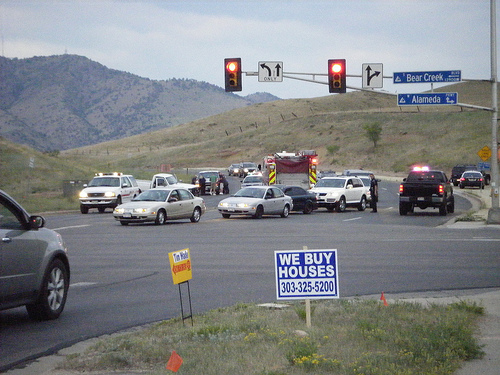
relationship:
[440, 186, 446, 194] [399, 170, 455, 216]
brake lights on back of pick up truck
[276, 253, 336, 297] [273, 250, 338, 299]
ad on sign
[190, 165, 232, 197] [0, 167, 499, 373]
auto accident on street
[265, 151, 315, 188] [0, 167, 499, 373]
emergency vehicle on street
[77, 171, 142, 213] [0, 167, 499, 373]
police car on side of street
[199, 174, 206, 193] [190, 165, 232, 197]
policeman next to auto accident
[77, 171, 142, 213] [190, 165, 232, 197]
emergency vehicle next to auto accident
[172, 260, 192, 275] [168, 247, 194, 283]
arrow on sign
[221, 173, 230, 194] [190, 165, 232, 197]
emergency personnel next to auto accident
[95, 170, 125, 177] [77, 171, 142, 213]
lights are on police car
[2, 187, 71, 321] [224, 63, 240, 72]
silver car in front of traffic light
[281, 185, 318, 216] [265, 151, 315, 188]
car next to emergency vehicle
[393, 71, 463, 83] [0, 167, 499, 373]
sign above street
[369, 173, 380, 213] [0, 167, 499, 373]
policeman on street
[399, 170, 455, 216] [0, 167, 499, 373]
pick up truck on street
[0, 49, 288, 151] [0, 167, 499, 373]
hill behind street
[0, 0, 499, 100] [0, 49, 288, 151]
sky above hill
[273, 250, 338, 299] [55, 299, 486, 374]
sign in grass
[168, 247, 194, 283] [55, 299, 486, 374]
sign in grass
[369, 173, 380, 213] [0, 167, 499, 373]
policeman on top of street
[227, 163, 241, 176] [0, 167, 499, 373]
car on street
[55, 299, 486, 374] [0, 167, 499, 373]
grass near street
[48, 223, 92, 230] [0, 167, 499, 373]
line on street